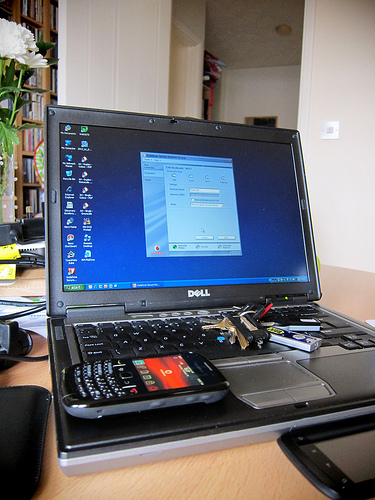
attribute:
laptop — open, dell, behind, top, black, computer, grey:
[4, 144, 358, 437]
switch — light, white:
[293, 119, 351, 170]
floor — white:
[321, 239, 364, 293]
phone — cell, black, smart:
[58, 327, 265, 441]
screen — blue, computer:
[89, 145, 278, 270]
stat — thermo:
[311, 105, 355, 171]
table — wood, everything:
[215, 457, 259, 487]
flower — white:
[2, 6, 49, 98]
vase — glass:
[2, 165, 50, 264]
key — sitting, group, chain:
[197, 289, 358, 383]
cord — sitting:
[2, 323, 74, 400]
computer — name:
[150, 269, 233, 316]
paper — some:
[31, 275, 72, 314]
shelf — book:
[9, 0, 65, 45]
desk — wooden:
[151, 429, 269, 498]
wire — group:
[8, 232, 62, 291]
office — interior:
[110, 15, 308, 153]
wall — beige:
[318, 21, 373, 80]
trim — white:
[179, 38, 205, 111]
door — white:
[59, 23, 165, 92]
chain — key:
[259, 323, 320, 359]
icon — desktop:
[53, 114, 130, 286]